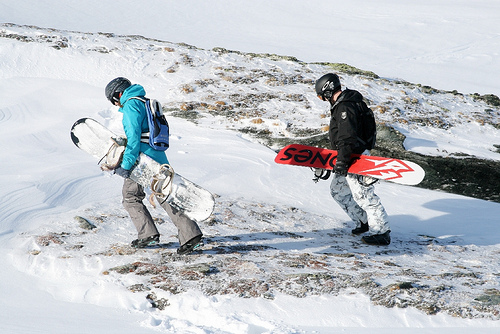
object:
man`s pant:
[121, 174, 203, 244]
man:
[315, 71, 394, 246]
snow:
[0, 22, 500, 333]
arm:
[334, 106, 359, 162]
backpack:
[344, 94, 378, 150]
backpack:
[125, 95, 173, 152]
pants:
[329, 147, 393, 237]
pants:
[121, 160, 206, 244]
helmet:
[314, 72, 342, 101]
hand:
[332, 160, 351, 177]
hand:
[112, 164, 133, 179]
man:
[104, 77, 205, 253]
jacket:
[120, 83, 169, 169]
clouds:
[0, 0, 500, 96]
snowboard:
[69, 117, 219, 224]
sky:
[0, 0, 500, 95]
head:
[314, 71, 343, 104]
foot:
[360, 230, 393, 244]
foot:
[350, 222, 370, 236]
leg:
[345, 162, 391, 230]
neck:
[326, 91, 342, 104]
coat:
[326, 86, 375, 164]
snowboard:
[272, 142, 426, 185]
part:
[67, 118, 88, 146]